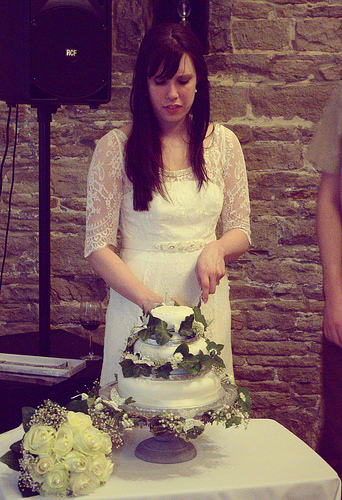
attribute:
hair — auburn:
[122, 21, 211, 211]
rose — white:
[73, 424, 103, 457]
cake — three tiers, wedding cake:
[113, 299, 226, 407]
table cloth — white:
[1, 417, 340, 499]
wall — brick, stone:
[0, 1, 341, 479]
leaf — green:
[0, 449, 23, 471]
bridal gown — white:
[82, 122, 253, 382]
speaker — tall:
[0, 0, 115, 358]